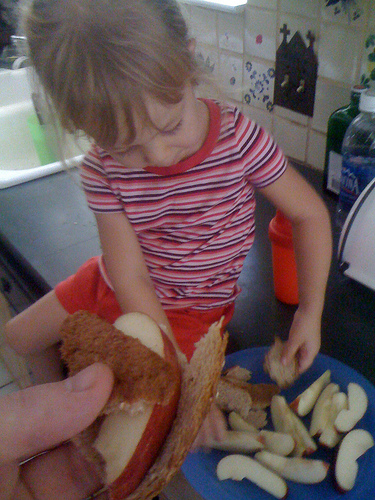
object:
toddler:
[5, 0, 331, 497]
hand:
[0, 363, 132, 499]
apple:
[93, 310, 178, 499]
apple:
[268, 392, 318, 462]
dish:
[180, 335, 372, 495]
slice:
[213, 451, 289, 496]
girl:
[5, 0, 352, 377]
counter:
[2, 130, 373, 499]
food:
[32, 301, 192, 403]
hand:
[283, 306, 323, 376]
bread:
[258, 332, 299, 389]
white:
[6, 98, 16, 125]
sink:
[0, 74, 26, 173]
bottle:
[334, 85, 374, 245]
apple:
[254, 399, 346, 464]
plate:
[197, 344, 373, 488]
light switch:
[295, 78, 306, 94]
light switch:
[279, 73, 289, 90]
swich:
[272, 61, 314, 116]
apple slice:
[334, 382, 369, 424]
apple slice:
[332, 428, 371, 488]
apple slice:
[289, 369, 338, 413]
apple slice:
[274, 384, 306, 452]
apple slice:
[259, 446, 330, 485]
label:
[336, 156, 363, 196]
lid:
[356, 90, 363, 101]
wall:
[192, 1, 363, 164]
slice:
[340, 424, 363, 496]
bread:
[56, 310, 231, 498]